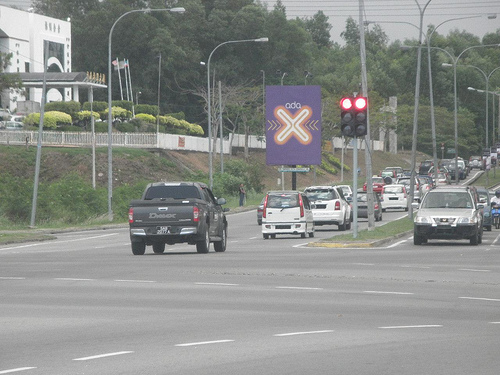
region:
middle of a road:
[289, 263, 302, 285]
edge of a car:
[442, 198, 450, 218]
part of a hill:
[94, 195, 104, 205]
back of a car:
[160, 223, 168, 243]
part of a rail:
[176, 136, 184, 144]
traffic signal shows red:
[336, 86, 373, 146]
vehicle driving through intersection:
[121, 176, 228, 251]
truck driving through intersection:
[131, 166, 232, 258]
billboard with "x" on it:
[262, 90, 324, 169]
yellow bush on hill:
[40, 99, 77, 131]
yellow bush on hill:
[76, 103, 103, 125]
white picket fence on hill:
[7, 125, 184, 151]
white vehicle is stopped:
[263, 190, 314, 241]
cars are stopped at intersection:
[421, 178, 486, 240]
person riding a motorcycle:
[482, 187, 499, 229]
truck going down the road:
[96, 171, 235, 256]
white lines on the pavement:
[179, 312, 396, 354]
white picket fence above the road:
[59, 120, 171, 156]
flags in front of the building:
[114, 53, 139, 105]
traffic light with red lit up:
[330, 91, 372, 143]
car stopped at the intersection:
[419, 146, 496, 236]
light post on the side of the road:
[99, 5, 206, 237]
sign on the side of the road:
[234, 83, 324, 179]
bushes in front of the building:
[53, 99, 197, 141]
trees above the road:
[124, 5, 291, 80]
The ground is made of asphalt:
[30, 279, 284, 334]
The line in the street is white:
[18, 256, 498, 313]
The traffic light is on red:
[337, 88, 368, 239]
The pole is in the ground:
[345, 146, 365, 240]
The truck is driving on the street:
[123, 178, 229, 258]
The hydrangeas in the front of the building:
[21, 103, 208, 139]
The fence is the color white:
[20, 124, 230, 155]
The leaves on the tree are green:
[136, 15, 313, 75]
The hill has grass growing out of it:
[4, 151, 126, 211]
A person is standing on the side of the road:
[230, 180, 251, 209]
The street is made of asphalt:
[36, 293, 260, 338]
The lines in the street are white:
[60, 268, 495, 313]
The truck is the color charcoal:
[121, 172, 233, 259]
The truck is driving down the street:
[126, 171, 232, 254]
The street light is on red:
[336, 91, 369, 142]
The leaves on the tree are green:
[133, 23, 198, 74]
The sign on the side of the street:
[258, 76, 329, 176]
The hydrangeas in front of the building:
[23, 101, 209, 138]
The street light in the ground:
[99, 6, 191, 225]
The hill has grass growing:
[9, 150, 115, 215]